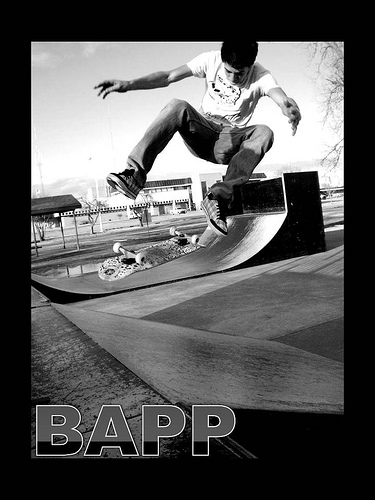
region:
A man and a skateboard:
[87, 34, 311, 284]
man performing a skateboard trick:
[87, 32, 310, 283]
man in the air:
[86, 31, 309, 239]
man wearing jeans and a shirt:
[90, 34, 308, 239]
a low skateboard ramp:
[6, 166, 329, 305]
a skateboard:
[94, 218, 221, 283]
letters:
[34, 392, 244, 452]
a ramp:
[189, 341, 232, 386]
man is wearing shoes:
[197, 195, 233, 241]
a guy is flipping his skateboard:
[51, 40, 303, 341]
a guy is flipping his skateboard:
[78, 33, 230, 231]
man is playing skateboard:
[61, 32, 332, 228]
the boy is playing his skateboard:
[77, 35, 274, 269]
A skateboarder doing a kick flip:
[36, 43, 335, 325]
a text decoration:
[34, 395, 238, 461]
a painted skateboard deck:
[84, 222, 234, 292]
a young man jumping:
[78, 44, 309, 243]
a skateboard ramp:
[190, 199, 300, 280]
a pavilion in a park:
[42, 182, 102, 247]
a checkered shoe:
[197, 181, 244, 247]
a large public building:
[106, 174, 214, 229]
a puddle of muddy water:
[53, 256, 103, 277]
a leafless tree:
[306, 41, 359, 179]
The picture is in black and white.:
[57, 57, 318, 370]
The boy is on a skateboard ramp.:
[120, 52, 281, 234]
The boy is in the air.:
[105, 58, 296, 258]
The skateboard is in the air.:
[74, 231, 206, 297]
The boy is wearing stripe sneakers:
[112, 167, 247, 228]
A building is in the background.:
[90, 175, 214, 228]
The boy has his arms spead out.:
[107, 65, 295, 120]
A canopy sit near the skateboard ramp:
[28, 195, 92, 254]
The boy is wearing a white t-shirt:
[178, 53, 279, 119]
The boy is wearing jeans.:
[157, 106, 268, 190]